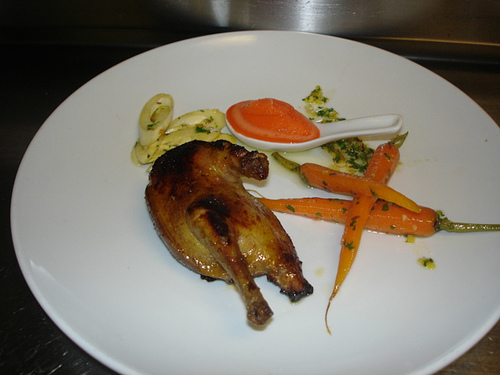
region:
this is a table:
[6, 328, 42, 361]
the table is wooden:
[11, 338, 43, 355]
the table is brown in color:
[460, 356, 484, 371]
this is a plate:
[79, 235, 144, 307]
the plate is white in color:
[73, 208, 121, 293]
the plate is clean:
[45, 229, 107, 277]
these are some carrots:
[286, 158, 469, 248]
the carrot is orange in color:
[368, 200, 387, 222]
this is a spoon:
[326, 115, 406, 141]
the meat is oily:
[175, 183, 241, 246]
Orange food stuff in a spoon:
[223, 90, 328, 154]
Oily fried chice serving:
[136, 139, 317, 331]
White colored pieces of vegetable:
[127, 90, 244, 167]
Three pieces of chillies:
[251, 135, 498, 342]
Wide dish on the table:
[0, 27, 497, 372]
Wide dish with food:
[0, 0, 499, 374]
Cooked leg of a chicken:
[182, 196, 280, 332]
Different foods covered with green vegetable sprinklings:
[133, 83, 498, 255]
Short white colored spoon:
[219, 100, 407, 157]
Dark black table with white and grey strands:
[2, 58, 499, 373]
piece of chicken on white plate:
[144, 140, 321, 317]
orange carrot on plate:
[318, 160, 415, 211]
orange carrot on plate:
[265, 190, 454, 228]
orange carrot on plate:
[333, 128, 388, 335]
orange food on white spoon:
[230, 91, 326, 144]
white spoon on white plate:
[219, 97, 415, 142]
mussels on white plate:
[125, 93, 219, 156]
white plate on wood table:
[0, 5, 498, 374]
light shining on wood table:
[227, 0, 357, 43]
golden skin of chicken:
[188, 200, 308, 260]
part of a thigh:
[243, 272, 272, 321]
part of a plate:
[116, 261, 155, 309]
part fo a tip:
[303, 295, 350, 338]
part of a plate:
[338, 234, 376, 309]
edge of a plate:
[423, 312, 484, 360]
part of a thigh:
[211, 224, 266, 316]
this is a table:
[454, 58, 493, 88]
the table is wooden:
[5, 319, 40, 354]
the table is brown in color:
[14, 329, 49, 366]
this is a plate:
[47, 215, 112, 281]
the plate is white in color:
[55, 210, 110, 273]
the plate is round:
[63, 205, 121, 258]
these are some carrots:
[261, 133, 469, 327]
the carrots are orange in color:
[357, 195, 400, 216]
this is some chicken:
[135, 142, 332, 325]